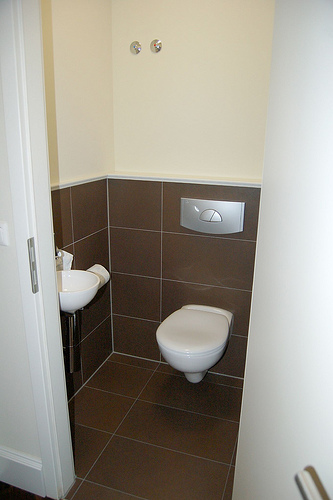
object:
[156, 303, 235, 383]
procelain toilet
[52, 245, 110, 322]
train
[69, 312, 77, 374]
pipe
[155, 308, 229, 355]
lid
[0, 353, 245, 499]
floor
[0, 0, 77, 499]
doorway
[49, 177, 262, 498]
tile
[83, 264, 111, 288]
toilet paper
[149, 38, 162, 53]
knob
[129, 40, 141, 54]
knob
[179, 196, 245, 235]
soap dispenser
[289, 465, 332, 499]
doorknob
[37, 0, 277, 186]
upper wall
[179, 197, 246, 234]
dispenser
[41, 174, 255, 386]
wall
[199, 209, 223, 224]
button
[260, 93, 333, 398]
white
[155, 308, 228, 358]
toilet seat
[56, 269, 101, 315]
sink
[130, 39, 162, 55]
buttons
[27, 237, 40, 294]
handle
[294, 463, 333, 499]
bar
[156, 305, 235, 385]
white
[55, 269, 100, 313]
urinal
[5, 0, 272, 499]
bathroom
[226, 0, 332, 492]
door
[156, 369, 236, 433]
shadow